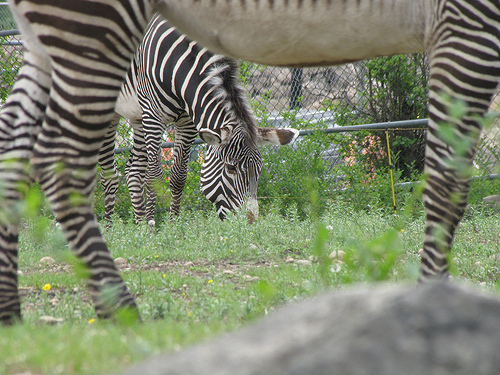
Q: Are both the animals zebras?
A: Yes, all the animals are zebras.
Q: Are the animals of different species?
A: No, all the animals are zebras.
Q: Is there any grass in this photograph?
A: Yes, there is grass.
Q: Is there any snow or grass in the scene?
A: Yes, there is grass.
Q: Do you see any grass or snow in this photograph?
A: Yes, there is grass.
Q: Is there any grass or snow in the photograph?
A: Yes, there is grass.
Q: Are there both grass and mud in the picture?
A: No, there is grass but no mud.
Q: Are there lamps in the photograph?
A: No, there are no lamps.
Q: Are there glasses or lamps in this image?
A: No, there are no lamps or glasses.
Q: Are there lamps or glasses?
A: No, there are no lamps or glasses.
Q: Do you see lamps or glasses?
A: No, there are no lamps or glasses.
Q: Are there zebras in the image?
A: Yes, there is a zebra.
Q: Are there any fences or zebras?
A: Yes, there is a zebra.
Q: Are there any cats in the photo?
A: No, there are no cats.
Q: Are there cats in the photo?
A: No, there are no cats.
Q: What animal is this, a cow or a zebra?
A: This is a zebra.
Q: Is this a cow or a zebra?
A: This is a zebra.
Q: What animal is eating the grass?
A: The zebra is eating the grass.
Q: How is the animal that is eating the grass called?
A: The animal is a zebra.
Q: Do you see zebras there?
A: Yes, there is a zebra.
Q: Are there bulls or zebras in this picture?
A: Yes, there is a zebra.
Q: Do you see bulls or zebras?
A: Yes, there is a zebra.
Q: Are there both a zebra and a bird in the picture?
A: No, there is a zebra but no birds.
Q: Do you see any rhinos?
A: No, there are no rhinos.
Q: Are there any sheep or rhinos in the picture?
A: No, there are no rhinos or sheep.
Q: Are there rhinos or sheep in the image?
A: No, there are no rhinos or sheep.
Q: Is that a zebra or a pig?
A: That is a zebra.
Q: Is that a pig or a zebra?
A: That is a zebra.